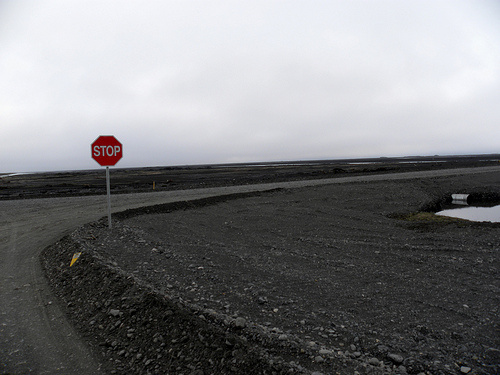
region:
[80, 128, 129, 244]
a stop sign in the dirt road.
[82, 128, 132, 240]
a stop sign in the dirt road.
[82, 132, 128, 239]
a stop sign in the dirt road.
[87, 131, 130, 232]
a stop sign in the dirt road.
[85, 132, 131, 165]
stop sign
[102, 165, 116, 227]
silver metal pole holding up stop sign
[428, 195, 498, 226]
puddle of water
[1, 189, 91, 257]
bend in the empty road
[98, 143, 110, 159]
the letter T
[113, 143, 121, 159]
the letter P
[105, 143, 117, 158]
the letter O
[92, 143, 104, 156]
the letter S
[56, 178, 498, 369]
empty barren field with only soil in it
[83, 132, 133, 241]
stop sign on the road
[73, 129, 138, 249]
stop sign on the road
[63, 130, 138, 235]
stop sign on the road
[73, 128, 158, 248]
stop sign on the road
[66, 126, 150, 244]
stop sign on the road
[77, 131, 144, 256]
stop sign on the road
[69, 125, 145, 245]
stop sign on the road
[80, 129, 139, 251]
stop sign on the road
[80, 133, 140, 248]
stop sign on the road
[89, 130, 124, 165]
The sign is red.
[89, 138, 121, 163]
The lettering is white.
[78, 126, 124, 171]
The edge is white.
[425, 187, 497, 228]
The water is still.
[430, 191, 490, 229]
The water is standing.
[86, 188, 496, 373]
The ground is rocky.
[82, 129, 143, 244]
the sign is on the side of the road.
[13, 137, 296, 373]
The road is a dirt road.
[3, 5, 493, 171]
The sky is cloudy.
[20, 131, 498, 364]
No one is on the road.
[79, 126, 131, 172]
a red stop sign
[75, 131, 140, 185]
a red stop sign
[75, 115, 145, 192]
a red stop sign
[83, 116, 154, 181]
a red stop sign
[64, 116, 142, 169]
a red stop sign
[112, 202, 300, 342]
the road is not paved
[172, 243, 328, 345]
the road is not paved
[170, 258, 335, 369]
the road is not paved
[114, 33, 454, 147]
a sky that is very grey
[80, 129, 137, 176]
a sign that is red and white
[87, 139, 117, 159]
the word stop written in white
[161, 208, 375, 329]
some dirt that is dark brown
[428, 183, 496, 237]
a pond that is small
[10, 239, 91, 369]
a road that is grey in color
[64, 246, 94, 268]
a small piece of yellow trash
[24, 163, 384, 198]
a field made out of dirt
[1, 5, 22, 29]
a small bit of blue sky